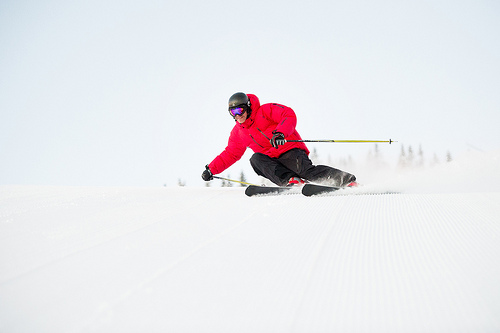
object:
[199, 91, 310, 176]
coat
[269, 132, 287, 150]
gloves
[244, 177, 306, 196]
skis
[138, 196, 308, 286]
snow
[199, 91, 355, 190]
man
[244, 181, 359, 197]
gear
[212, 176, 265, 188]
poles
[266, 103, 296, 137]
hands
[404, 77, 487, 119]
sky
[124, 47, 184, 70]
clouds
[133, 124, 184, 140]
clouds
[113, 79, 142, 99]
clouds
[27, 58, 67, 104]
clouds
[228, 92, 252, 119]
helmet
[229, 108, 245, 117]
googles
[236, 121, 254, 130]
hood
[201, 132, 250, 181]
hands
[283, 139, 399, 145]
poles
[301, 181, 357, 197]
ski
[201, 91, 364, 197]
skier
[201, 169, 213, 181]
glove